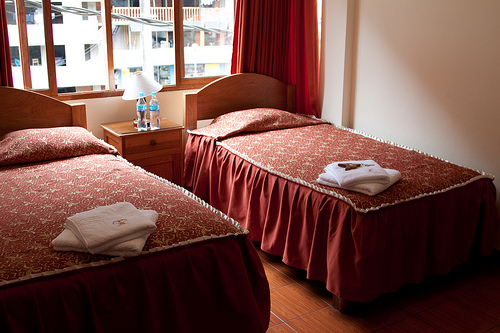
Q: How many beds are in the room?
A: Two.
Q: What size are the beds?
A: Twin.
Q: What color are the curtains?
A: Red.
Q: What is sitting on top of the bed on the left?
A: Towels.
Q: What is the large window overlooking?
A: A neighbor.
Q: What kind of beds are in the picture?
A: Twin.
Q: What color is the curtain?
A: Red.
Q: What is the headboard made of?
A: Wood.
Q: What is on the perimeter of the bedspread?
A: Ribbing.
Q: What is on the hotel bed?
A: Fancy towels.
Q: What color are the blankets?
A: Red.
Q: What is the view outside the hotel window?
A: Apartments.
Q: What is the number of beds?
A: Two.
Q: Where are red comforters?
A: On beds.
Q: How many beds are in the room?
A: Two.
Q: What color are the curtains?
A: Red.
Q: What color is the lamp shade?
A: White.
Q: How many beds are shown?
A: Two.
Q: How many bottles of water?
A: Two.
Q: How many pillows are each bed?
A: One.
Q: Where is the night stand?
A: Between the beds.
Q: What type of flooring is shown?
A: Tile.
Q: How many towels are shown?
A: Four.